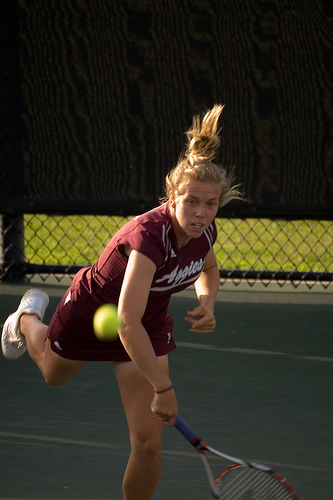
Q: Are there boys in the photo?
A: No, there are no boys.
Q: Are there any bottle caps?
A: No, there are no bottle caps.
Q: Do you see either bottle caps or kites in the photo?
A: No, there are no bottle caps or kites.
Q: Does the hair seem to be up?
A: Yes, the hair is up.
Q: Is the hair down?
A: No, the hair is up.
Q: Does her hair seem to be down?
A: No, the hair is up.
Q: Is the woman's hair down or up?
A: The hair is up.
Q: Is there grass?
A: Yes, there is grass.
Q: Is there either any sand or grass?
A: Yes, there is grass.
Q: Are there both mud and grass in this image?
A: No, there is grass but no mud.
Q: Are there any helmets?
A: No, there are no helmets.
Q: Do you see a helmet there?
A: No, there are no helmets.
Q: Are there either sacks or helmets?
A: No, there are no helmets or sacks.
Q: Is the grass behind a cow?
A: No, the grass is behind the fence.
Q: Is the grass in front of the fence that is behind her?
A: No, the grass is behind the fence.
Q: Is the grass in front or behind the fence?
A: The grass is behind the fence.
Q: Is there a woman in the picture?
A: Yes, there is a woman.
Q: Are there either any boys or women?
A: Yes, there is a woman.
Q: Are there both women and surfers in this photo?
A: No, there is a woman but no surfers.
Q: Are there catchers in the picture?
A: No, there are no catchers.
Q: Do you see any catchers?
A: No, there are no catchers.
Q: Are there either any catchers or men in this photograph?
A: No, there are no catchers or men.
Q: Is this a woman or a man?
A: This is a woman.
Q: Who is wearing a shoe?
A: The woman is wearing a shoe.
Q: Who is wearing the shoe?
A: The woman is wearing a shoe.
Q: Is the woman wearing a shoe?
A: Yes, the woman is wearing a shoe.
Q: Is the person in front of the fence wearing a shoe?
A: Yes, the woman is wearing a shoe.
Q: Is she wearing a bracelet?
A: No, the woman is wearing a shoe.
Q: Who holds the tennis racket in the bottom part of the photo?
A: The woman holds the racket.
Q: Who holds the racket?
A: The woman holds the racket.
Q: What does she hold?
A: The woman holds the racket.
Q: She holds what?
A: The woman holds the racket.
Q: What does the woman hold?
A: The woman holds the racket.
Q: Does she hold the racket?
A: Yes, the woman holds the racket.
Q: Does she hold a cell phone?
A: No, the woman holds the racket.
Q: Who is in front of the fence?
A: The woman is in front of the fence.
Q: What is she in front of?
A: The woman is in front of the fence.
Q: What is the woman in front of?
A: The woman is in front of the fence.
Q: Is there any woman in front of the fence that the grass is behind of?
A: Yes, there is a woman in front of the fence.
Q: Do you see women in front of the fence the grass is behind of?
A: Yes, there is a woman in front of the fence.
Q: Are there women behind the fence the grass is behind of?
A: No, the woman is in front of the fence.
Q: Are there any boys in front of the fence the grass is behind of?
A: No, there is a woman in front of the fence.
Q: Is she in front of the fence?
A: Yes, the woman is in front of the fence.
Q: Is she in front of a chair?
A: No, the woman is in front of the fence.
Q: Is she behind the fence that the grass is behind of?
A: No, the woman is in front of the fence.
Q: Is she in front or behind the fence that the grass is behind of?
A: The woman is in front of the fence.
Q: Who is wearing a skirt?
A: The woman is wearing a skirt.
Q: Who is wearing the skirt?
A: The woman is wearing a skirt.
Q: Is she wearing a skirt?
A: Yes, the woman is wearing a skirt.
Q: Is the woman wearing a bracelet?
A: No, the woman is wearing a skirt.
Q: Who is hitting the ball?
A: The woman is hitting the ball.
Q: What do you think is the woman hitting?
A: The woman is hitting the ball.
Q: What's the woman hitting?
A: The woman is hitting the ball.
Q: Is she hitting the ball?
A: Yes, the woman is hitting the ball.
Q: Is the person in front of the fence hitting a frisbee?
A: No, the woman is hitting the ball.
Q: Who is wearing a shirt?
A: The woman is wearing a shirt.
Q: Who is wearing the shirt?
A: The woman is wearing a shirt.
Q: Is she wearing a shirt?
A: Yes, the woman is wearing a shirt.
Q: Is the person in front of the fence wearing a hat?
A: No, the woman is wearing a shirt.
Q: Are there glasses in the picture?
A: No, there are no glasses.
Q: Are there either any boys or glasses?
A: No, there are no glasses or boys.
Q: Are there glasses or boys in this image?
A: No, there are no glasses or boys.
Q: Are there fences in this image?
A: Yes, there is a fence.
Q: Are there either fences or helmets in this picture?
A: Yes, there is a fence.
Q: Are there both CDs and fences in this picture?
A: No, there is a fence but no cds.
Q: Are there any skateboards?
A: No, there are no skateboards.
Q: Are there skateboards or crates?
A: No, there are no skateboards or crates.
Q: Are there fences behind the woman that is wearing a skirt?
A: Yes, there is a fence behind the woman.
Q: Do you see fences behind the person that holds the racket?
A: Yes, there is a fence behind the woman.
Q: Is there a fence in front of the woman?
A: No, the fence is behind the woman.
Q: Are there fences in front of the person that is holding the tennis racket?
A: No, the fence is behind the woman.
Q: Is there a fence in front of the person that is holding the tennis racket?
A: No, the fence is behind the woman.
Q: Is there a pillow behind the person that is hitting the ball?
A: No, there is a fence behind the woman.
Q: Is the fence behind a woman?
A: Yes, the fence is behind a woman.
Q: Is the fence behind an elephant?
A: No, the fence is behind a woman.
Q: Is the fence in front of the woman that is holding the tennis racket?
A: No, the fence is behind the woman.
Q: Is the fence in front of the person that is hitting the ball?
A: No, the fence is behind the woman.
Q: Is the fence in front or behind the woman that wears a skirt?
A: The fence is behind the woman.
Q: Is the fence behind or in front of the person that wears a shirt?
A: The fence is behind the woman.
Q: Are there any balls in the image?
A: Yes, there is a ball.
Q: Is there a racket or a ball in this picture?
A: Yes, there is a ball.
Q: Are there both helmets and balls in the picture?
A: No, there is a ball but no helmets.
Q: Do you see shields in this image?
A: No, there are no shields.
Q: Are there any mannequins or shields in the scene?
A: No, there are no shields or mannequins.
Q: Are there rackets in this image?
A: Yes, there is a racket.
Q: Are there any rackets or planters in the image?
A: Yes, there is a racket.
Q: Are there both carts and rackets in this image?
A: No, there is a racket but no carts.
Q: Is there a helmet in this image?
A: No, there are no helmets.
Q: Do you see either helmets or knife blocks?
A: No, there are no helmets or knife blocks.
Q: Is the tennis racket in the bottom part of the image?
A: Yes, the tennis racket is in the bottom of the image.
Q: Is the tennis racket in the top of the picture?
A: No, the tennis racket is in the bottom of the image.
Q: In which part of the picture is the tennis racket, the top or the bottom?
A: The tennis racket is in the bottom of the image.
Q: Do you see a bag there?
A: No, there are no bags.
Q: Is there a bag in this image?
A: No, there are no bags.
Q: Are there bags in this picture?
A: No, there are no bags.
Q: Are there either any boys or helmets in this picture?
A: No, there are no helmets or boys.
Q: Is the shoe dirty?
A: Yes, the shoe is dirty.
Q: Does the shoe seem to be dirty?
A: Yes, the shoe is dirty.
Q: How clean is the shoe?
A: The shoe is dirty.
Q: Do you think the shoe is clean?
A: No, the shoe is dirty.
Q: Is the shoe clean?
A: No, the shoe is dirty.